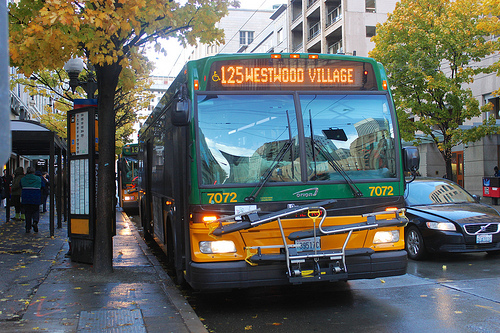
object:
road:
[193, 249, 499, 333]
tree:
[364, 0, 496, 180]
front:
[187, 51, 406, 288]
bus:
[137, 51, 421, 292]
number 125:
[220, 66, 244, 84]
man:
[20, 167, 44, 232]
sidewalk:
[2, 209, 205, 333]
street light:
[62, 57, 83, 95]